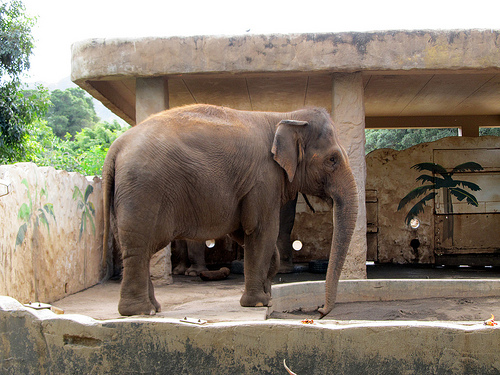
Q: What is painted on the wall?
A: A palm tree.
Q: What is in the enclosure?
A: A large gray elephant.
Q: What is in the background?
A: The back wall to the zoo enclosure.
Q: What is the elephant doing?
A: The elephant is standing in place.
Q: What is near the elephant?
A: A cement structure.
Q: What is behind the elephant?
A: A stone wall.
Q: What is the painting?
A: A painting of a palm tree.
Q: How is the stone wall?
A: The stone wall is faded.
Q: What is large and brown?
A: An elephant.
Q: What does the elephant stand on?
A: Four legs.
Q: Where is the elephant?
A: In an enclosure.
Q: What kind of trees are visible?
A: Palm trees.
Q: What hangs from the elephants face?
A: A trunk.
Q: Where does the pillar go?
A: From ground to the roof.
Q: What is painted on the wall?
A: Trees.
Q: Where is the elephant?
A: In an enclosure.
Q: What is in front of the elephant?
A: A stone wall.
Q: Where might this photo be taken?
A: Zoo.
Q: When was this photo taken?
A: Daytime.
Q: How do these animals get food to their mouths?
A: With trunks.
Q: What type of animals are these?
A: Elephants.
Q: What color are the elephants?
A: Gray.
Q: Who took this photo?
A: Photographer.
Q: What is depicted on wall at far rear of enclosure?
A: Palm tree.